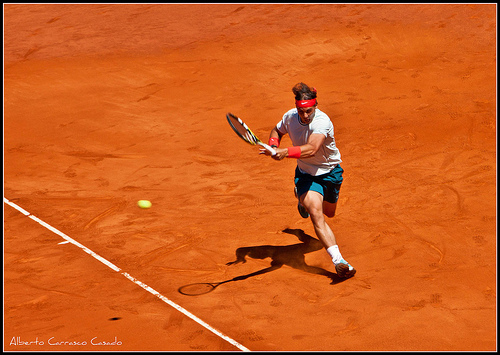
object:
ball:
[138, 198, 151, 210]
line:
[0, 198, 248, 350]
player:
[258, 82, 357, 276]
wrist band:
[286, 145, 301, 158]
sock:
[327, 245, 347, 264]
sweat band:
[294, 98, 316, 107]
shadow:
[179, 228, 346, 297]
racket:
[225, 112, 276, 156]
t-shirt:
[275, 106, 342, 175]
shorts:
[294, 164, 343, 203]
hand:
[271, 146, 290, 162]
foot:
[333, 258, 360, 277]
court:
[0, 3, 498, 350]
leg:
[298, 181, 355, 276]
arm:
[272, 124, 335, 161]